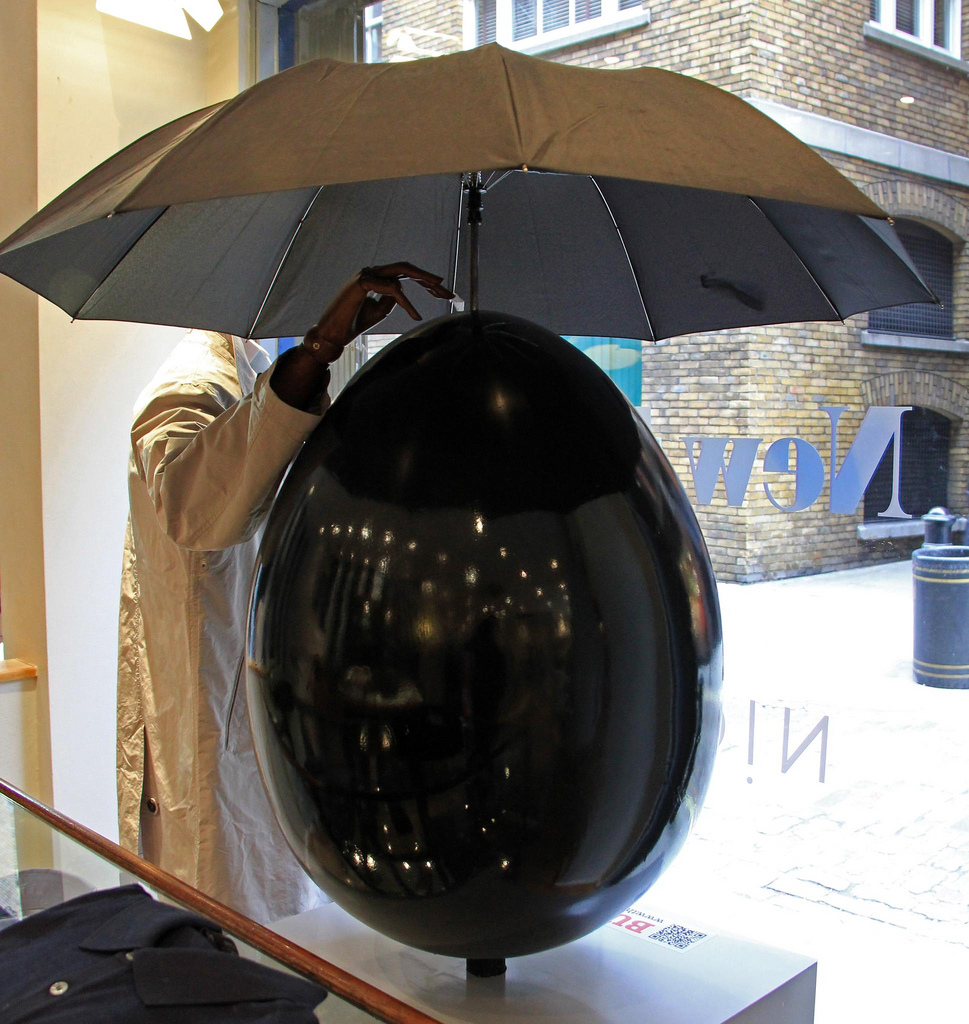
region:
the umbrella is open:
[4, 1, 937, 380]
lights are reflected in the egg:
[231, 437, 603, 938]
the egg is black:
[199, 281, 725, 980]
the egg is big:
[143, 274, 764, 968]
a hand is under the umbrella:
[128, 213, 503, 599]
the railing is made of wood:
[114, 843, 422, 1016]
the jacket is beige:
[89, 307, 335, 813]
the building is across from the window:
[735, 4, 928, 628]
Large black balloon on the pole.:
[274, 309, 703, 962]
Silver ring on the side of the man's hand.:
[351, 278, 386, 283]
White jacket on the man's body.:
[135, 323, 337, 979]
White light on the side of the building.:
[96, 1, 253, 31]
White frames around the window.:
[863, 0, 959, 66]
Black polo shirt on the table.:
[11, 898, 199, 1017]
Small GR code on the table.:
[653, 918, 700, 956]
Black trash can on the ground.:
[897, 511, 963, 677]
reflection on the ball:
[335, 577, 548, 892]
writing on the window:
[767, 401, 899, 514]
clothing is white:
[118, 568, 253, 810]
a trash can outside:
[915, 550, 968, 674]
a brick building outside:
[750, 343, 809, 414]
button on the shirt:
[46, 973, 81, 1004]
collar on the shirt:
[148, 957, 225, 997]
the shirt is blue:
[160, 955, 218, 1006]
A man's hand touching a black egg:
[278, 253, 513, 387]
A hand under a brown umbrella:
[13, 32, 948, 344]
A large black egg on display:
[241, 282, 736, 989]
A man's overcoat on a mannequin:
[98, 332, 313, 932]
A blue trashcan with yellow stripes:
[903, 516, 966, 713]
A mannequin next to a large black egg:
[93, 250, 754, 943]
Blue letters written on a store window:
[654, 383, 964, 565]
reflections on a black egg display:
[288, 307, 711, 1001]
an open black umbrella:
[0, 38, 956, 378]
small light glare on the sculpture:
[397, 850, 416, 873]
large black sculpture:
[250, 300, 724, 986]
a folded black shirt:
[4, 873, 326, 1022]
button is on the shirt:
[49, 973, 66, 1000]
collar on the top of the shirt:
[71, 881, 304, 1022]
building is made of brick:
[369, 2, 968, 605]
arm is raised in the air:
[139, 246, 483, 564]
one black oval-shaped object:
[243, 298, 728, 970]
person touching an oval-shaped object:
[116, 260, 733, 972]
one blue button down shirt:
[2, 878, 316, 1021]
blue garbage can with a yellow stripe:
[909, 534, 967, 695]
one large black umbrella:
[0, 42, 956, 338]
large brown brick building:
[372, 0, 964, 577]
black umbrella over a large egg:
[0, 37, 942, 978]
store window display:
[6, 35, 934, 1020]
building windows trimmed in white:
[862, 4, 964, 59]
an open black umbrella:
[92, 39, 865, 488]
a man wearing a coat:
[110, 252, 451, 692]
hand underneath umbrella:
[301, 259, 446, 375]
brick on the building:
[747, 419, 794, 454]